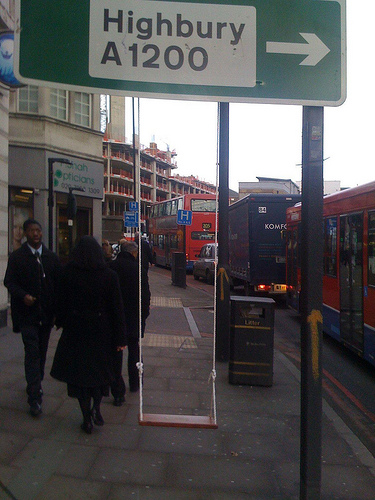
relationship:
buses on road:
[153, 171, 229, 258] [331, 354, 348, 384]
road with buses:
[331, 354, 348, 384] [153, 171, 229, 258]